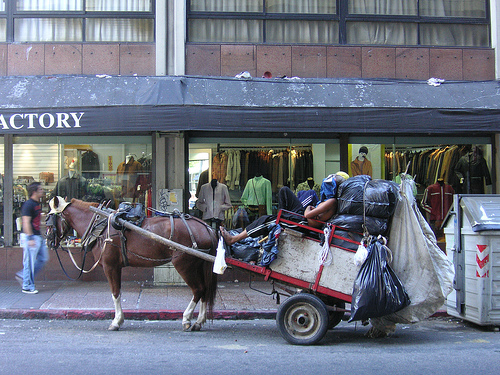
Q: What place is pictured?
A: It is a shop.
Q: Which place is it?
A: It is a shop.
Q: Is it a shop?
A: Yes, it is a shop.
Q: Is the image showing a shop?
A: Yes, it is showing a shop.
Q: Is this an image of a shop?
A: Yes, it is showing a shop.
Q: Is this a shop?
A: Yes, it is a shop.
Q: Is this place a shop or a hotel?
A: It is a shop.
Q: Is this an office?
A: No, it is a shop.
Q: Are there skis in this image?
A: No, there are no skis.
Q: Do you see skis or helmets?
A: No, there are no skis or helmets.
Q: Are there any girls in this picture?
A: No, there are no girls.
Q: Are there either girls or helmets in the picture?
A: No, there are no girls or helmets.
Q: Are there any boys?
A: No, there are no boys.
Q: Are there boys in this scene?
A: No, there are no boys.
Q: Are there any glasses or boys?
A: No, there are no boys or glasses.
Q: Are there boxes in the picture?
A: No, there are no boxes.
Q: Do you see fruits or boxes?
A: No, there are no boxes or fruits.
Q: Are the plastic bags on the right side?
A: Yes, the bags are on the right of the image.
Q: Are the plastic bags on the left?
A: No, the bags are on the right of the image.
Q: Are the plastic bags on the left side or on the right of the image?
A: The bags are on the right of the image.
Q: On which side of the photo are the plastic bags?
A: The bags are on the right of the image.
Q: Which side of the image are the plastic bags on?
A: The bags are on the right of the image.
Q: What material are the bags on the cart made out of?
A: The bags are made of plastic.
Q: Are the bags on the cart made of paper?
A: No, the bags are made of plastic.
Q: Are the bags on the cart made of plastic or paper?
A: The bags are made of plastic.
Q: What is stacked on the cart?
A: The bags are stacked on the cart.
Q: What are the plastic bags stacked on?
A: The bags are stacked on the cart.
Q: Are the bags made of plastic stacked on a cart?
A: Yes, the bags are stacked on a cart.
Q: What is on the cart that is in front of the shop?
A: The bags are on the cart.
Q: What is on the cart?
A: The bags are on the cart.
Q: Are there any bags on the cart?
A: Yes, there are bags on the cart.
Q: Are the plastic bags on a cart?
A: Yes, the bags are on a cart.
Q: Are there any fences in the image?
A: No, there are no fences.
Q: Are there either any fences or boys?
A: No, there are no fences or boys.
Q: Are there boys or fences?
A: No, there are no fences or boys.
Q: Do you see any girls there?
A: No, there are no girls.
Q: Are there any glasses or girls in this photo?
A: No, there are no girls or glasses.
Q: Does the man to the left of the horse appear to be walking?
A: Yes, the man is walking.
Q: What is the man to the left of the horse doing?
A: The man is walking.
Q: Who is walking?
A: The man is walking.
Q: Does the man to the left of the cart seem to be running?
A: No, the man is walking.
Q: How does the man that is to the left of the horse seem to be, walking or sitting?
A: The man is walking.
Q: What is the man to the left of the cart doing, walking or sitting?
A: The man is walking.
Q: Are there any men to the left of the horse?
A: Yes, there is a man to the left of the horse.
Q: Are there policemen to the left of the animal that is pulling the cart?
A: No, there is a man to the left of the horse.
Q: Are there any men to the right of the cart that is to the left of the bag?
A: No, the man is to the left of the cart.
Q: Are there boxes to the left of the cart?
A: No, there is a man to the left of the cart.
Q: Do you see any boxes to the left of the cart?
A: No, there is a man to the left of the cart.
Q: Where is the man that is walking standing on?
A: The man is standing on the side walk.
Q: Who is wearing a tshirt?
A: The man is wearing a tshirt.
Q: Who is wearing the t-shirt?
A: The man is wearing a tshirt.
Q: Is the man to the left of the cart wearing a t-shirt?
A: Yes, the man is wearing a t-shirt.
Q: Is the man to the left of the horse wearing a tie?
A: No, the man is wearing a t-shirt.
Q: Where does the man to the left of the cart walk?
A: The man walks on the sidewalk.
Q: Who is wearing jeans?
A: The man is wearing jeans.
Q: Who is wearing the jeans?
A: The man is wearing jeans.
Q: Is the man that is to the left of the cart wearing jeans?
A: Yes, the man is wearing jeans.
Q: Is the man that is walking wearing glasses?
A: No, the man is wearing jeans.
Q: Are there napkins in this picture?
A: No, there are no napkins.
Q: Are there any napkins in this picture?
A: No, there are no napkins.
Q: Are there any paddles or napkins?
A: No, there are no napkins or paddles.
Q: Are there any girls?
A: No, there are no girls.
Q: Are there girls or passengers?
A: No, there are no girls or passengers.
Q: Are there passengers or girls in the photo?
A: No, there are no girls or passengers.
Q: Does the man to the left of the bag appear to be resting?
A: Yes, the man is resting.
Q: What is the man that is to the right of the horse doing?
A: The man is resting.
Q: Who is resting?
A: The man is resting.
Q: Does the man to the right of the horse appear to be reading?
A: No, the man is resting.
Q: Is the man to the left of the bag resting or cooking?
A: The man is resting.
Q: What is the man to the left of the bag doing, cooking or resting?
A: The man is resting.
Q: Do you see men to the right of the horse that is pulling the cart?
A: Yes, there is a man to the right of the horse.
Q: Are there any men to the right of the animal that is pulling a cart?
A: Yes, there is a man to the right of the horse.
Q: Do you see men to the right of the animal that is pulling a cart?
A: Yes, there is a man to the right of the horse.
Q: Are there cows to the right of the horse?
A: No, there is a man to the right of the horse.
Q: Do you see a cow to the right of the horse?
A: No, there is a man to the right of the horse.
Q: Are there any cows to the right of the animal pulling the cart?
A: No, there is a man to the right of the horse.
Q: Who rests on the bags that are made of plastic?
A: The man rests on the bags.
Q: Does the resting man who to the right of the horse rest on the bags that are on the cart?
A: Yes, the man rests on the bags.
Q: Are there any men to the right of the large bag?
A: No, the man is to the left of the bag.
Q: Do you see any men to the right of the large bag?
A: No, the man is to the left of the bag.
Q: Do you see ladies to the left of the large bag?
A: No, there is a man to the left of the bag.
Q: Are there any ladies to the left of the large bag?
A: No, there is a man to the left of the bag.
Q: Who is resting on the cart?
A: The man is resting on the cart.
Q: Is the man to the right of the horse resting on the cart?
A: Yes, the man is resting on the cart.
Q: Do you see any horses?
A: Yes, there is a horse.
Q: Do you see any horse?
A: Yes, there is a horse.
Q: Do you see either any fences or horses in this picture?
A: Yes, there is a horse.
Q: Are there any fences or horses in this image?
A: Yes, there is a horse.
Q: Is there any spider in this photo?
A: No, there are no spiders.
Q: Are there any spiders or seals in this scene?
A: No, there are no spiders or seals.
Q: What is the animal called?
A: The animal is a horse.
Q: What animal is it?
A: The animal is a horse.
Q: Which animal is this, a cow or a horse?
A: This is a horse.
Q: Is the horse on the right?
A: No, the horse is on the left of the image.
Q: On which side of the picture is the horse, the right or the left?
A: The horse is on the left of the image.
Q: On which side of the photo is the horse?
A: The horse is on the left of the image.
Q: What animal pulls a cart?
A: The horse pulls a cart.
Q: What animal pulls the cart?
A: The horse pulls a cart.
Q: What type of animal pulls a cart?
A: The animal is a horse.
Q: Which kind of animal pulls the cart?
A: The animal is a horse.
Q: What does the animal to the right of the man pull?
A: The horse pulls a cart.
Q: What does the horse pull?
A: The horse pulls a cart.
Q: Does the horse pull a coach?
A: No, the horse pulls a cart.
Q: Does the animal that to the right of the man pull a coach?
A: No, the horse pulls a cart.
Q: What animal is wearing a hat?
A: The horse is wearing a hat.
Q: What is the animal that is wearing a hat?
A: The animal is a horse.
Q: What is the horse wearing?
A: The horse is wearing a hat.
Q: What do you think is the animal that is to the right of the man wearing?
A: The horse is wearing a hat.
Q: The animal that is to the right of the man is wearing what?
A: The horse is wearing a hat.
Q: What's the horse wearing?
A: The horse is wearing a hat.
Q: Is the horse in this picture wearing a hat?
A: Yes, the horse is wearing a hat.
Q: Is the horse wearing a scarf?
A: No, the horse is wearing a hat.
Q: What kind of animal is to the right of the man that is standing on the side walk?
A: The animal is a horse.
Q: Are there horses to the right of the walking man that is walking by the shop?
A: Yes, there is a horse to the right of the man.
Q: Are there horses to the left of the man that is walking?
A: No, the horse is to the right of the man.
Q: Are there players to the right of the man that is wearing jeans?
A: No, there is a horse to the right of the man.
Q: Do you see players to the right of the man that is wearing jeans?
A: No, there is a horse to the right of the man.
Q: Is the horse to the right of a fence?
A: No, the horse is to the right of a man.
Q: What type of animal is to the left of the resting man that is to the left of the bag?
A: The animal is a horse.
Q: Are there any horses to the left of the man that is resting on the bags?
A: Yes, there is a horse to the left of the man.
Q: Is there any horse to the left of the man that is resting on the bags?
A: Yes, there is a horse to the left of the man.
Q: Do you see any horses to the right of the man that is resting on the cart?
A: No, the horse is to the left of the man.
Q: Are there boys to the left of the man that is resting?
A: No, there is a horse to the left of the man.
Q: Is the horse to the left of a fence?
A: No, the horse is to the left of the man.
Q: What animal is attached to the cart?
A: The horse is attached to the cart.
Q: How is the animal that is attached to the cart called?
A: The animal is a horse.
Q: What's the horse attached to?
A: The horse is attached to the cart.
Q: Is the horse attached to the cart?
A: Yes, the horse is attached to the cart.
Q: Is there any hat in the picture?
A: Yes, there is a hat.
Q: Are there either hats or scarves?
A: Yes, there is a hat.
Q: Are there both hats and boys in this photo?
A: No, there is a hat but no boys.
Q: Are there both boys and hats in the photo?
A: No, there is a hat but no boys.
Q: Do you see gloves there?
A: No, there are no gloves.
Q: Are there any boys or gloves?
A: No, there are no gloves or boys.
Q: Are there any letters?
A: Yes, there are letters.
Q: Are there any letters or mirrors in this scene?
A: Yes, there are letters.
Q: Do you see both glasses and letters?
A: No, there are letters but no glasses.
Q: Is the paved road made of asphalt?
A: Yes, the road is made of asphalt.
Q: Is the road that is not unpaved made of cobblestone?
A: No, the road is made of asphalt.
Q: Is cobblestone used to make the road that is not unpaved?
A: No, the road is made of asphalt.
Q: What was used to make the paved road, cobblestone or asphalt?
A: The road is made of asphalt.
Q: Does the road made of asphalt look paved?
A: Yes, the road is paved.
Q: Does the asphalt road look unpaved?
A: No, the road is paved.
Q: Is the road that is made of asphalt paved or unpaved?
A: The road is paved.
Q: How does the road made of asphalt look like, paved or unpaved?
A: The road is paved.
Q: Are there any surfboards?
A: No, there are no surfboards.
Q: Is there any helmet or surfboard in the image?
A: No, there are no surfboards or helmets.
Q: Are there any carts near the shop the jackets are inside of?
A: Yes, there is a cart near the shop.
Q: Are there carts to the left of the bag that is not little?
A: Yes, there is a cart to the left of the bag.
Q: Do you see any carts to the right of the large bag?
A: No, the cart is to the left of the bag.